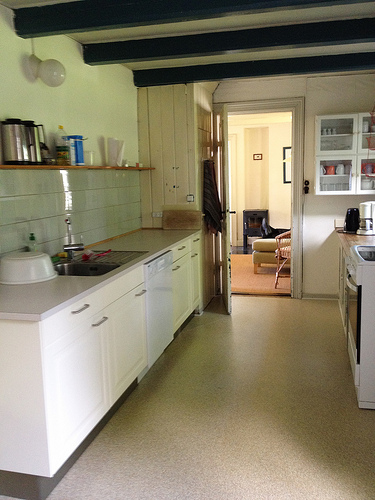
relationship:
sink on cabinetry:
[41, 234, 123, 285] [0, 224, 203, 500]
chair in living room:
[277, 221, 299, 292] [223, 110, 295, 290]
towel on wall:
[203, 156, 222, 236] [195, 84, 226, 306]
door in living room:
[210, 100, 301, 297] [226, 128, 298, 307]